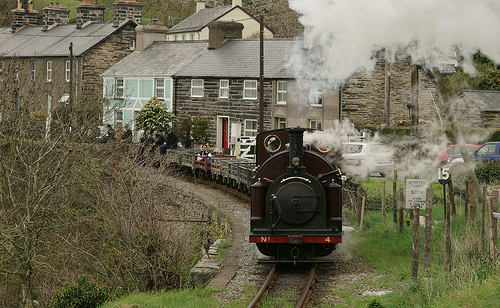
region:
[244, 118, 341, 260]
the front of a train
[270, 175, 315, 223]
the large circle of a train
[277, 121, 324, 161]
the chimney of a train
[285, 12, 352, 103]
the steam coming out of a train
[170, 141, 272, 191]
a bunch of small train cars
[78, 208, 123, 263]
a bunch of wild grass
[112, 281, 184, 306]
a patch of light green grass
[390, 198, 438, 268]
a small wooden post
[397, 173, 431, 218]
a black and white sign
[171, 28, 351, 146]
a big two story house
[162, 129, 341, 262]
this is a train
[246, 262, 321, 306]
this is the rail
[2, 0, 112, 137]
this is a building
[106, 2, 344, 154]
this is a building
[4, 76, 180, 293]
vegetation by the road side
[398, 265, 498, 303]
vegetation by the road side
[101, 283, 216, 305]
vegetation by the road side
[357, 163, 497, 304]
this is a fence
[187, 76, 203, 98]
this is a window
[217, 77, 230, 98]
this is a winmdow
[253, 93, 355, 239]
this is a train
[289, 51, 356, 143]
this is a fumes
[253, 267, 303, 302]
this is the railway line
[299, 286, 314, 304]
this is a metal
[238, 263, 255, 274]
these are small rocks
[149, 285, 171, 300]
this is a grass area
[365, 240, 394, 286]
the grass is green in color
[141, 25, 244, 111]
this is a house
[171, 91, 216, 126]
this is the wall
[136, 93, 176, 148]
this is a tree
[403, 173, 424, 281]
a white sign next to the train tracks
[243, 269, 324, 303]
train tracks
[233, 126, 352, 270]
a train on the train tracks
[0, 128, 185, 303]
trees next to the train tracks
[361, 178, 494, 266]
a wooden fence next to the train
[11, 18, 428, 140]
buildings behind the train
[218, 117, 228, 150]
a red door on the building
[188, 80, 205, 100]
a window on the building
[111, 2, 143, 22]
the chimney on the building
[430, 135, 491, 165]
cars next to the fence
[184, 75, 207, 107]
This is a window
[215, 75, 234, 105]
This is a window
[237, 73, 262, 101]
This is a window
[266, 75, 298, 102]
This is a window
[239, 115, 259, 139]
This is a window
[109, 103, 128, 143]
This is a window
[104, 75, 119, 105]
This is a window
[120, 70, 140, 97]
This is a window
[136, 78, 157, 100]
This is a window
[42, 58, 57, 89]
This is a window